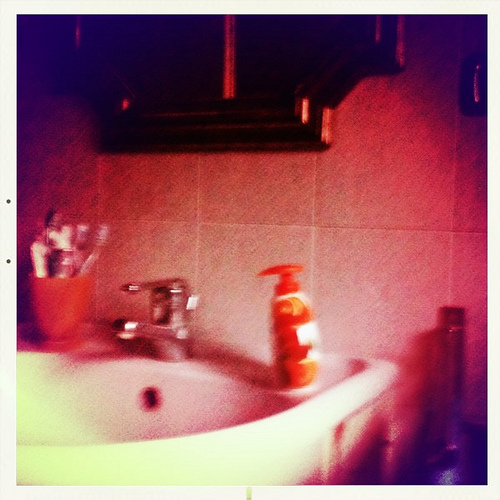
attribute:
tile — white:
[310, 222, 454, 352]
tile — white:
[195, 222, 317, 354]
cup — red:
[29, 272, 95, 343]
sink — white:
[19, 327, 395, 483]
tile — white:
[112, 166, 291, 270]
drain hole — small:
[141, 385, 162, 413]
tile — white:
[201, 151, 316, 223]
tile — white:
[95, 220, 200, 332]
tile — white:
[93, 155, 196, 225]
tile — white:
[95, 162, 200, 227]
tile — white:
[210, 153, 319, 223]